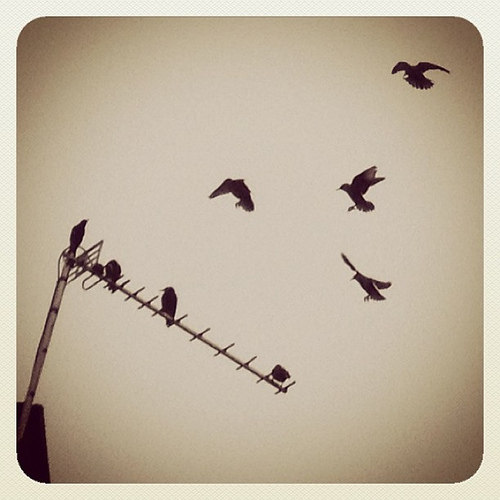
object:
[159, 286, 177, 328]
birds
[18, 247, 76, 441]
pole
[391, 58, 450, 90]
bird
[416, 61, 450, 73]
its wings spread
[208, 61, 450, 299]
four birds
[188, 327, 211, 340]
lines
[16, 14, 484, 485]
sky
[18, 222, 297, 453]
part of a stand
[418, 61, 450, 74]
left wing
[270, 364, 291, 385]
bird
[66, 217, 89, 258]
blackbird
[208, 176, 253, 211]
bird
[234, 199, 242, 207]
claws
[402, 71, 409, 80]
beak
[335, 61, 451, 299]
three birds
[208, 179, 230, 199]
wings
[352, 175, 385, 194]
feathers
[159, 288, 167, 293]
beak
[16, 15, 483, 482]
photo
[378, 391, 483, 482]
dark part